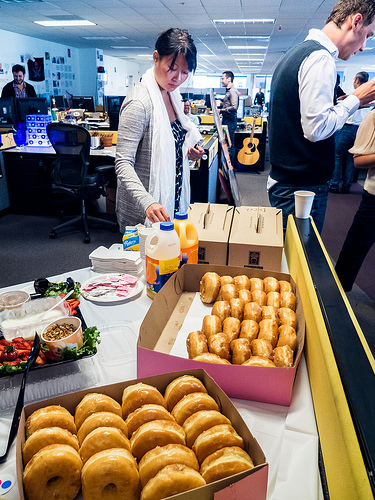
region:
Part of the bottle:
[158, 241, 170, 259]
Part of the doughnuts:
[238, 289, 250, 307]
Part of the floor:
[27, 237, 45, 263]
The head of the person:
[148, 24, 198, 94]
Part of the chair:
[60, 140, 66, 153]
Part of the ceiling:
[116, 9, 139, 21]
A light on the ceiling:
[30, 16, 97, 30]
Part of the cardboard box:
[243, 227, 258, 243]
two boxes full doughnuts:
[14, 259, 306, 499]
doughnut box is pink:
[135, 263, 306, 407]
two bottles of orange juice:
[144, 210, 199, 299]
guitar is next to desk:
[236, 112, 260, 174]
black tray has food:
[0, 276, 100, 380]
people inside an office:
[1, 2, 373, 293]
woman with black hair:
[113, 25, 204, 233]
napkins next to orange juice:
[89, 244, 144, 276]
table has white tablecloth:
[1, 228, 328, 498]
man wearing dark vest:
[265, 0, 374, 238]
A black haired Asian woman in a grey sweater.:
[115, 27, 204, 237]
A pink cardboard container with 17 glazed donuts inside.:
[12, 366, 268, 498]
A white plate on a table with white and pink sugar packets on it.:
[81, 273, 145, 303]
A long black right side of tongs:
[0, 331, 41, 461]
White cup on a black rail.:
[293, 189, 316, 218]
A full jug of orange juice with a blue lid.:
[170, 211, 199, 265]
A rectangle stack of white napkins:
[88, 245, 144, 274]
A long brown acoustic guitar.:
[237, 113, 259, 166]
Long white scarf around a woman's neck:
[142, 67, 199, 221]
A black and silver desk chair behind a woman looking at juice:
[42, 122, 123, 243]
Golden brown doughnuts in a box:
[21, 413, 64, 488]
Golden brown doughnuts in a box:
[77, 389, 133, 492]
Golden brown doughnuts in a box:
[117, 379, 192, 496]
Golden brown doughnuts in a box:
[148, 367, 245, 495]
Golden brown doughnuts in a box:
[189, 346, 289, 377]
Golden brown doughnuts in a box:
[188, 329, 297, 359]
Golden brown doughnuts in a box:
[202, 309, 295, 343]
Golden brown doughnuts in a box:
[209, 300, 295, 321]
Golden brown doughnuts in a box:
[219, 281, 312, 314]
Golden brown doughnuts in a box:
[194, 264, 301, 292]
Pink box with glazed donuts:
[135, 260, 306, 406]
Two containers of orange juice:
[143, 212, 200, 302]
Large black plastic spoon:
[2, 331, 42, 467]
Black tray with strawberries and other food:
[2, 283, 97, 371]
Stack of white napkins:
[87, 245, 148, 276]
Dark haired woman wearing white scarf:
[114, 27, 210, 237]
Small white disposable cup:
[290, 188, 316, 221]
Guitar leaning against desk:
[229, 118, 266, 174]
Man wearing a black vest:
[256, 3, 374, 234]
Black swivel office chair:
[42, 119, 120, 243]